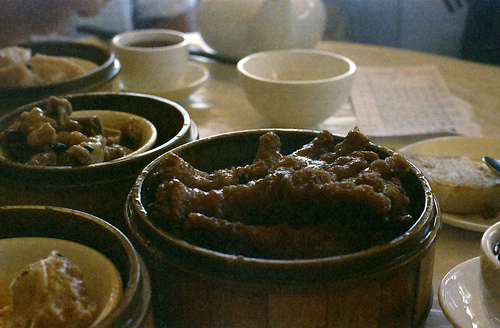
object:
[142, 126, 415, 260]
food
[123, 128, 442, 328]
bowl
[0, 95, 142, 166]
food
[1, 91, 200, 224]
bowl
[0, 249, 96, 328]
food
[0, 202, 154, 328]
bowl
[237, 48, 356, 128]
bowl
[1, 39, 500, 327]
table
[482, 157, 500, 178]
spoon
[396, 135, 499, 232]
plate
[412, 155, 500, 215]
cake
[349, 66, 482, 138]
napkin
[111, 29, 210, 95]
coffee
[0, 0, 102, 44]
hand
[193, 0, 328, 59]
pitcher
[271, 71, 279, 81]
light reflection